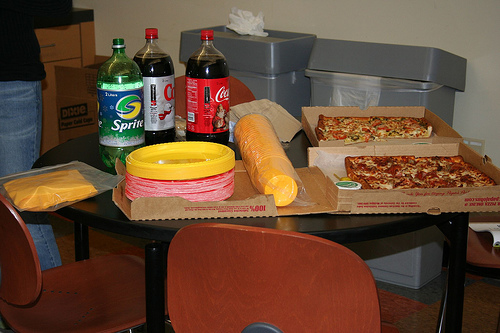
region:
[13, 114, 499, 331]
Two pizzas on top of a black table.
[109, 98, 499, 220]
Pizzas in cardboard boxes.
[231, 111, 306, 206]
Yellow plastic cups lying on a pizza box lid.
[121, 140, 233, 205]
Pink and yellow plates sitting on the pizza box lid.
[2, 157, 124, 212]
Yellow napkins in a clear plastic bag.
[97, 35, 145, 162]
Green bottle of soda with no lid.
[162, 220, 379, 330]
Back of a brown wooden chair.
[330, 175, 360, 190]
Container of dipping sauce in the pizza box.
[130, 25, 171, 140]
Soda bottle with a gray label.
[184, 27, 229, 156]
Bottle of soda with a red label.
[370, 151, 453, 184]
this is a pizza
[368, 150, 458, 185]
the pizza is flat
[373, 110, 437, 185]
the pizza are two in number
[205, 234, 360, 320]
this is the chair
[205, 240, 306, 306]
the chair is wooden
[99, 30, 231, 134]
these are bottles of soda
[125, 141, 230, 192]
these are piles of plates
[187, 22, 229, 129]
the bottle is big in size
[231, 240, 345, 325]
the chair is wooden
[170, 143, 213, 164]
the plate is yellow in color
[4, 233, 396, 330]
A brown color chairs near the table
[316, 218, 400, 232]
Black color wooden table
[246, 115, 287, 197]
Yellow color water glass kept above the table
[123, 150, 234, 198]
Red and yellow color plates kept above the table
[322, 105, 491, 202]
Two large size pizza kept in the table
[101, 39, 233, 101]
Three cooldrinks boottle kept in the table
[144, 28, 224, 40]
Lid of the boottles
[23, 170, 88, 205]
Yellow color napkin kept in the table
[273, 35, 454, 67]
A plastic boxes near the wall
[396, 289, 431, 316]
Brown color wooden type floor tiles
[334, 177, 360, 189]
garlic butter by in pizza box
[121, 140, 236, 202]
yellow and red plastic plates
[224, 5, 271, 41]
white paper towel on garbage can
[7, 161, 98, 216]
yellow napkins in plastic zipper bag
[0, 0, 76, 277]
person standing by pizza on table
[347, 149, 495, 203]
pizza on round wood table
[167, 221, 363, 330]
red wood chair under dark wood table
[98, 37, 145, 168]
two liter drink with missing cap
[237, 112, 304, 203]
roll of yellow plastic cups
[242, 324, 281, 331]
metal bracket on back of chair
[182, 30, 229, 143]
the 2 liter coke bottle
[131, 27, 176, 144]
the 2 liter diet coke bottle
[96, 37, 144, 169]
the 2 liter sprite bottle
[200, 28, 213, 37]
the red cap to the coke bottle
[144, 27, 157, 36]
the red cap on the diet coke bottle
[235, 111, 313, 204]
the package of stacked yellow cups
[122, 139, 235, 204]
the stack of yellow and red plates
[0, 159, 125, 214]
the ziploc filled with yellow napkins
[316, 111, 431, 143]
the pizza in the box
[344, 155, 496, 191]
the pizza in the box